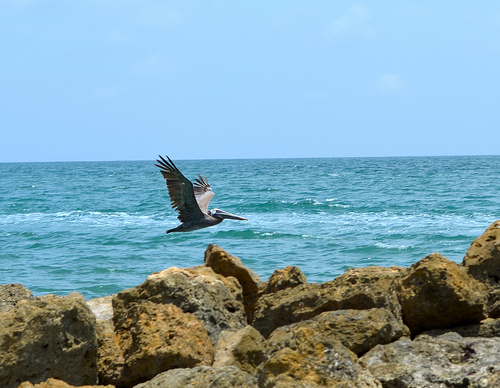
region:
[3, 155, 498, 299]
a large body of water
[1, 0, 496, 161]
a section of blue sky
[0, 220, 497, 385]
large rocks on the shore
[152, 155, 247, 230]
a bird in flight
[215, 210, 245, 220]
the bird's long beak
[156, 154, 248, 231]
a bird with wings outstretched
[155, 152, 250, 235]
a bird flying through the air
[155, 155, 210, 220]
the wings of a flying bird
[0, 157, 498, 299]
a section of blue ocean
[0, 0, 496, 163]
a cloudless blue sky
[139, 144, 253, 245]
bird flying by an ocean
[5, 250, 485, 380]
rocks by an ocean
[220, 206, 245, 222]
beak of a bird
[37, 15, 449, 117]
blue sky in the distance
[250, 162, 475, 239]
blue water of an ocean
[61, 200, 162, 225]
wave in an ocean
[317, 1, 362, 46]
cloud in a sky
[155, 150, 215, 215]
wings of a bird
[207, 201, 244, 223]
head of a bird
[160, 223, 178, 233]
feet of a bird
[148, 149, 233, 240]
gray bird flying over water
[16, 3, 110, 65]
white clouds in blue sky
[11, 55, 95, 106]
white clouds in blue sky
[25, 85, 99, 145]
white clouds in blue sky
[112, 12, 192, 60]
white clouds in blue sky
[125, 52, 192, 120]
white clouds in blue sky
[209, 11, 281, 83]
white clouds in blue sky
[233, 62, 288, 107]
white clouds in blue sky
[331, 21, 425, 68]
white clouds in blue sky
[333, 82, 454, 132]
white clouds in blue sky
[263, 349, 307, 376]
Rusty green on a rock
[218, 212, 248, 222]
Bill on a flying bird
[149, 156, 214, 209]
Feathers on a bird's wings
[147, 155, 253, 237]
Bird flying over rocks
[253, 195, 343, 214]
Small wave in an ocean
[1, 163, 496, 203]
Calm blue ocean water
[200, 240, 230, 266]
Sharp point on a rock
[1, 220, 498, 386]
Pile of rocks in front of the ocean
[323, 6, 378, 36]
White cloud in the sky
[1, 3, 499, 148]
Blue sky over an ocean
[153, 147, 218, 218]
grey seabird's wings outspread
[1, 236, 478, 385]
rocks by the sea shore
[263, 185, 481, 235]
waves in the ocean water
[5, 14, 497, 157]
clear open blue sky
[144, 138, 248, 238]
grey seabird flying above rocks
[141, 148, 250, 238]
grey seabird flying near ocean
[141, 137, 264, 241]
grey seabird flying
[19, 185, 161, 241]
waves in the ocean water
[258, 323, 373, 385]
rock covered in moss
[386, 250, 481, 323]
rock covered in moss